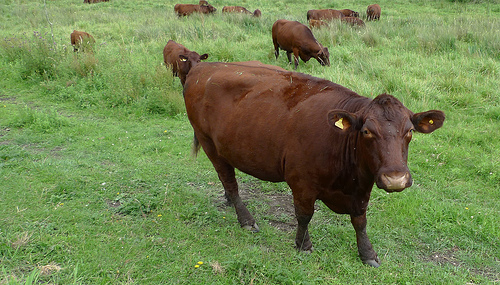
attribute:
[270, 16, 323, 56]
cow — brown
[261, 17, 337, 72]
cow — brown, large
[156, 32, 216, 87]
cow — large, brown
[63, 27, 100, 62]
cow — brown, large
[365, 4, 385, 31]
cow — large, brown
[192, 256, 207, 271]
pedals — yellow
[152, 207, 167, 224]
pedals — yellow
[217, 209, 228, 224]
pedals — yellow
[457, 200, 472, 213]
pedals — yellow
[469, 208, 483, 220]
pedals — yellow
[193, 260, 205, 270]
flower — yellow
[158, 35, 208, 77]
cow — brown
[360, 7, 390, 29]
cow — brown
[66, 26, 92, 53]
cow — brown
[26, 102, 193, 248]
path — grassy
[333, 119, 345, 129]
tags — yellow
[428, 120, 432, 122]
tags — yellow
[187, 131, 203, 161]
tail — brown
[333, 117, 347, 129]
tab — round, yellow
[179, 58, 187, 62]
tab — yellow, round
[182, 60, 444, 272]
cow — brown, large, big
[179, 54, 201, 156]
tail — black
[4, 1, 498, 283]
grass — tall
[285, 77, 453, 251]
cow — brown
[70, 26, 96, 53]
cow — brown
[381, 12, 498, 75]
grass — taller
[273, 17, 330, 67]
cow — small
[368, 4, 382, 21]
cow — small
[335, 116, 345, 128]
tag — yellow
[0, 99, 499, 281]
flowers — yellow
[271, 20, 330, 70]
cow — brown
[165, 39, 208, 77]
cow — small